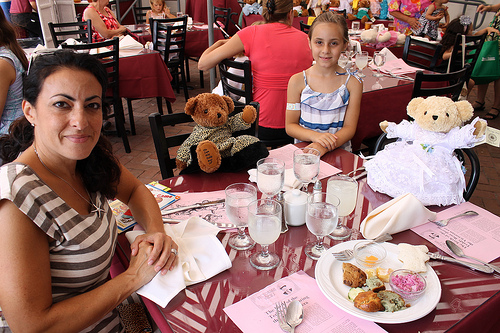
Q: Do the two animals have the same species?
A: Yes, all the animals are bears.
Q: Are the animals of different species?
A: No, all the animals are bears.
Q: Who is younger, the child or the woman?
A: The child is younger than the woman.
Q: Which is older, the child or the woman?
A: The woman is older than the child.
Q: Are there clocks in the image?
A: No, there are no clocks.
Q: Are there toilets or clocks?
A: No, there are no clocks or toilets.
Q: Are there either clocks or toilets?
A: No, there are no clocks or toilets.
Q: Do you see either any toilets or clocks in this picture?
A: No, there are no clocks or toilets.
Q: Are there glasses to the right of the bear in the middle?
A: Yes, there are glasses to the right of the bear.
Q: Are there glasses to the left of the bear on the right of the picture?
A: Yes, there are glasses to the left of the bear.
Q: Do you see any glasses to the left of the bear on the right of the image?
A: Yes, there are glasses to the left of the bear.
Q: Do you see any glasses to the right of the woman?
A: Yes, there are glasses to the right of the woman.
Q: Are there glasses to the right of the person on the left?
A: Yes, there are glasses to the right of the woman.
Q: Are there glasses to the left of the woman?
A: No, the glasses are to the right of the woman.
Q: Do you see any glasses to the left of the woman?
A: No, the glasses are to the right of the woman.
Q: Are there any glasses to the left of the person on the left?
A: No, the glasses are to the right of the woman.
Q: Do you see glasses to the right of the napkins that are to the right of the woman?
A: Yes, there are glasses to the right of the napkins.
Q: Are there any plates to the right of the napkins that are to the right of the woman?
A: No, there are glasses to the right of the napkins.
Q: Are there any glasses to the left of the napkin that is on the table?
A: Yes, there are glasses to the left of the napkin.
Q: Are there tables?
A: Yes, there is a table.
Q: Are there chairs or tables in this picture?
A: Yes, there is a table.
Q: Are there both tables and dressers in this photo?
A: No, there is a table but no dressers.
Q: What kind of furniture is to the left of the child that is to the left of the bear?
A: The piece of furniture is a table.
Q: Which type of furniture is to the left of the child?
A: The piece of furniture is a table.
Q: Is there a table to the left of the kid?
A: Yes, there is a table to the left of the kid.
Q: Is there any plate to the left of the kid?
A: No, there is a table to the left of the kid.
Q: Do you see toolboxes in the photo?
A: No, there are no toolboxes.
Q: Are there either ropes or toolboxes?
A: No, there are no toolboxes or ropes.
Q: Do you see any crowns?
A: No, there are no crowns.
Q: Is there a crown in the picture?
A: No, there are no crowns.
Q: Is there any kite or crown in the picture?
A: No, there are no crowns or kites.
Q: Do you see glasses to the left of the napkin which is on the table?
A: Yes, there are glasses to the left of the napkin.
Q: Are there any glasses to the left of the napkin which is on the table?
A: Yes, there are glasses to the left of the napkin.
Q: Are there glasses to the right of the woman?
A: Yes, there are glasses to the right of the woman.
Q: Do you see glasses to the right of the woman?
A: Yes, there are glasses to the right of the woman.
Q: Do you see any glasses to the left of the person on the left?
A: No, the glasses are to the right of the woman.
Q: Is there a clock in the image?
A: No, there are no clocks.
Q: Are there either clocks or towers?
A: No, there are no clocks or towers.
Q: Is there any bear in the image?
A: Yes, there is a bear.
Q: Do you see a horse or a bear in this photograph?
A: Yes, there is a bear.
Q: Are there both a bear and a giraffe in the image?
A: No, there is a bear but no giraffes.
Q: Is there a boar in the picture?
A: No, there are no boars.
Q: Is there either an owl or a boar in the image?
A: No, there are no boars or owls.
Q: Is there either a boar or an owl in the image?
A: No, there are no boars or owls.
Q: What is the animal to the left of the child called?
A: The animal is a bear.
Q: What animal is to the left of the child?
A: The animal is a bear.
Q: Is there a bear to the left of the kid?
A: Yes, there is a bear to the left of the kid.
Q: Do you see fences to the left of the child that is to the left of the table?
A: No, there is a bear to the left of the kid.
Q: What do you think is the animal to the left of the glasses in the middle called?
A: The animal is a bear.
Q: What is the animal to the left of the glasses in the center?
A: The animal is a bear.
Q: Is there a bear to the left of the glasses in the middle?
A: Yes, there is a bear to the left of the glasses.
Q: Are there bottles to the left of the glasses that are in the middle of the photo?
A: No, there is a bear to the left of the glasses.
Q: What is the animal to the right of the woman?
A: The animal is a bear.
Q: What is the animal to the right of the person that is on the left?
A: The animal is a bear.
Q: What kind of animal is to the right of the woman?
A: The animal is a bear.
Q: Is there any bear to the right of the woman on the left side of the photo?
A: Yes, there is a bear to the right of the woman.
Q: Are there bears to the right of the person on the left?
A: Yes, there is a bear to the right of the woman.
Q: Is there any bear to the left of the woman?
A: No, the bear is to the right of the woman.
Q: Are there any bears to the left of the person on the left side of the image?
A: No, the bear is to the right of the woman.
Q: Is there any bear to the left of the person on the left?
A: No, the bear is to the right of the woman.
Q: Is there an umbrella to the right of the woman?
A: No, there is a bear to the right of the woman.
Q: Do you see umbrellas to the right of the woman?
A: No, there is a bear to the right of the woman.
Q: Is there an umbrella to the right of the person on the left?
A: No, there is a bear to the right of the woman.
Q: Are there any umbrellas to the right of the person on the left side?
A: No, there is a bear to the right of the woman.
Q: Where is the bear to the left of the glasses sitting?
A: The bear is sitting at the table.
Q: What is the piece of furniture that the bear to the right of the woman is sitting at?
A: The piece of furniture is a table.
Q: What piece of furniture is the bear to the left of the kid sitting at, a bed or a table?
A: The bear is sitting at a table.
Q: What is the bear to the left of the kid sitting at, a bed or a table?
A: The bear is sitting at a table.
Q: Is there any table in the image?
A: Yes, there is a table.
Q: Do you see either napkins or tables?
A: Yes, there is a table.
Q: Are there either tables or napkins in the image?
A: Yes, there is a table.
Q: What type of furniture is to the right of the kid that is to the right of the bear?
A: The piece of furniture is a table.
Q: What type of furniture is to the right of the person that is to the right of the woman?
A: The piece of furniture is a table.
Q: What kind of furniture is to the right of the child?
A: The piece of furniture is a table.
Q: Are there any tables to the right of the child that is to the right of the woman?
A: Yes, there is a table to the right of the kid.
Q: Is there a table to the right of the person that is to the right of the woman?
A: Yes, there is a table to the right of the kid.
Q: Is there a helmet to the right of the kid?
A: No, there is a table to the right of the kid.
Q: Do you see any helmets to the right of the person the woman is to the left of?
A: No, there is a table to the right of the kid.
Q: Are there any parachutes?
A: No, there are no parachutes.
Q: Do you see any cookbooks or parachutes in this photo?
A: No, there are no parachutes or cookbooks.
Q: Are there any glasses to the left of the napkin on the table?
A: Yes, there are glasses to the left of the napkin.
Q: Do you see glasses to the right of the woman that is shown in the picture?
A: Yes, there are glasses to the right of the woman.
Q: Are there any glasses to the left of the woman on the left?
A: No, the glasses are to the right of the woman.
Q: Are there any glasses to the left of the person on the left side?
A: No, the glasses are to the right of the woman.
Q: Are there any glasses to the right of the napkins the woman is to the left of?
A: Yes, there are glasses to the right of the napkins.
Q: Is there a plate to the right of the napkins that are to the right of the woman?
A: No, there are glasses to the right of the napkins.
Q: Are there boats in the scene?
A: No, there are no boats.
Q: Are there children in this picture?
A: Yes, there is a child.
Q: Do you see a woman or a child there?
A: Yes, there is a child.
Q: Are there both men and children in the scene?
A: No, there is a child but no men.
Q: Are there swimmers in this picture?
A: No, there are no swimmers.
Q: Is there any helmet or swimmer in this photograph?
A: No, there are no swimmers or helmets.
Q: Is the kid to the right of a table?
A: Yes, the kid is to the right of a table.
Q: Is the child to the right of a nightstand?
A: No, the child is to the right of a table.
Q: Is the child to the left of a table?
A: No, the child is to the right of a table.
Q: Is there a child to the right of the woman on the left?
A: Yes, there is a child to the right of the woman.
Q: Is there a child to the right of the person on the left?
A: Yes, there is a child to the right of the woman.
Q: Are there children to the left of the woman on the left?
A: No, the child is to the right of the woman.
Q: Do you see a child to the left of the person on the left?
A: No, the child is to the right of the woman.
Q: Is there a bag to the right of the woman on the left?
A: No, there is a child to the right of the woman.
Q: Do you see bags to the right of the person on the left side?
A: No, there is a child to the right of the woman.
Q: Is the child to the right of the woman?
A: Yes, the child is to the right of the woman.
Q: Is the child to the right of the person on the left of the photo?
A: Yes, the child is to the right of the woman.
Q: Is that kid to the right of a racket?
A: No, the kid is to the right of the woman.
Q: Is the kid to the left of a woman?
A: No, the kid is to the right of a woman.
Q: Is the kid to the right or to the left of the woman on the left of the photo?
A: The kid is to the right of the woman.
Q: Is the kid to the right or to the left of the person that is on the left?
A: The kid is to the right of the woman.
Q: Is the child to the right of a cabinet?
A: No, the child is to the right of a table.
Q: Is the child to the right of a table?
A: No, the child is to the left of a table.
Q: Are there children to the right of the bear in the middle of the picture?
A: Yes, there is a child to the right of the bear.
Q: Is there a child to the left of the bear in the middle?
A: No, the child is to the right of the bear.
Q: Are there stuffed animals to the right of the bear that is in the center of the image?
A: No, there is a child to the right of the bear.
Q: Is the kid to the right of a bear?
A: Yes, the kid is to the right of a bear.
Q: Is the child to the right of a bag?
A: No, the child is to the right of a bear.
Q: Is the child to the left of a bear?
A: No, the child is to the right of a bear.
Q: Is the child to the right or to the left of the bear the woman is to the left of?
A: The child is to the right of the bear.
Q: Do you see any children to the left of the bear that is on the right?
A: Yes, there is a child to the left of the bear.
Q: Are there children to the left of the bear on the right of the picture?
A: Yes, there is a child to the left of the bear.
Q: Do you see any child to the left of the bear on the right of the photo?
A: Yes, there is a child to the left of the bear.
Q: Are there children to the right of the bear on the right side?
A: No, the child is to the left of the bear.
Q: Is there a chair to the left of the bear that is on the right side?
A: No, there is a child to the left of the bear.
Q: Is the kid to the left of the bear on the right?
A: Yes, the kid is to the left of the bear.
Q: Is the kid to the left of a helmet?
A: No, the kid is to the left of the bear.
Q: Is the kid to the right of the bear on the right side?
A: No, the kid is to the left of the bear.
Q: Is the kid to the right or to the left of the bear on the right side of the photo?
A: The kid is to the left of the bear.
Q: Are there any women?
A: Yes, there is a woman.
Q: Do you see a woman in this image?
A: Yes, there is a woman.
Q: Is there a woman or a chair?
A: Yes, there is a woman.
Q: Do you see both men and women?
A: No, there is a woman but no men.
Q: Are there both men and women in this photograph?
A: No, there is a woman but no men.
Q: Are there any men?
A: No, there are no men.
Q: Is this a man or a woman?
A: This is a woman.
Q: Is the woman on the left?
A: Yes, the woman is on the left of the image.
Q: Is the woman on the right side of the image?
A: No, the woman is on the left of the image.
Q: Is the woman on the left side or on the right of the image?
A: The woman is on the left of the image.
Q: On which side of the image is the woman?
A: The woman is on the left of the image.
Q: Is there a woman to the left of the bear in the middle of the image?
A: Yes, there is a woman to the left of the bear.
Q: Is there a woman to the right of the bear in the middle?
A: No, the woman is to the left of the bear.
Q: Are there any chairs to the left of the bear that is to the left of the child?
A: No, there is a woman to the left of the bear.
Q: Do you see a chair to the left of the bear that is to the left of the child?
A: No, there is a woman to the left of the bear.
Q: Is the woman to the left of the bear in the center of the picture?
A: Yes, the woman is to the left of the bear.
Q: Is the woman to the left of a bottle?
A: No, the woman is to the left of the bear.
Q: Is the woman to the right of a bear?
A: No, the woman is to the left of a bear.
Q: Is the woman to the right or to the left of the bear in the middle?
A: The woman is to the left of the bear.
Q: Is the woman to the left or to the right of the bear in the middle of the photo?
A: The woman is to the left of the bear.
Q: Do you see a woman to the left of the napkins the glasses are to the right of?
A: Yes, there is a woman to the left of the napkins.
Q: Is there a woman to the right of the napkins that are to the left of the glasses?
A: No, the woman is to the left of the napkins.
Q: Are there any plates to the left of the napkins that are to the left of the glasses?
A: No, there is a woman to the left of the napkins.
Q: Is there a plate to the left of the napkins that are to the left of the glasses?
A: No, there is a woman to the left of the napkins.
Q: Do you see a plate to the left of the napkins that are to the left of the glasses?
A: No, there is a woman to the left of the napkins.